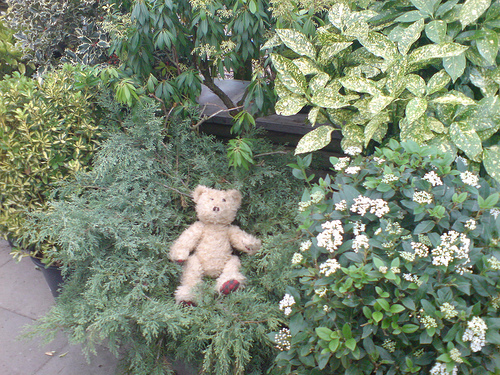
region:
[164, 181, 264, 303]
A teddy bear in the bushes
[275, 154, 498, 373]
bush on bottom right has yellow flowers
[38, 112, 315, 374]
The bear is laying on a fern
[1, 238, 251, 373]
The ground is grey bricks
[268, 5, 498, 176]
Leaves on the top right bush are green and yellow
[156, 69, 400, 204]
Stone wall is behind the bushes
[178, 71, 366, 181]
The stone wall is slate and black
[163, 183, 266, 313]
The bear is furry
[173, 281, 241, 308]
The bottom of his paws are plaid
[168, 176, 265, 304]
The bear is white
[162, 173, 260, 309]
A brown teddy bear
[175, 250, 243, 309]
The bottom of the teddy bears feet are red and black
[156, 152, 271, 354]
The teddy bear lies on top of a bush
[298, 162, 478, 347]
A bush with clusters of white flowers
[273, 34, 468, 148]
A tree with green and yellow leaves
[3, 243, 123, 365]
A grey tiled sidewalk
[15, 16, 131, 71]
Green leaves with yellow borders around them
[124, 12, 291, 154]
A tree with long thin leaves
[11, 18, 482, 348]
A planter next to the sidewalk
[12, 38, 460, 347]
A row of green bushes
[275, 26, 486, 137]
the leaves are green and white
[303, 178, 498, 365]
the white flowers are small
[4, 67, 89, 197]
the bush is green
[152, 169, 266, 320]
the bear is brown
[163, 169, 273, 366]
the bear is not wearing clothes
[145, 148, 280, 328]
the bear is in a bush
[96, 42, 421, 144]
there is a bench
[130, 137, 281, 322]
the bear is laying in the bush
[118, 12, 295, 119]
the tree is green with small leaves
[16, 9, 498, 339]
many greenery surround the bear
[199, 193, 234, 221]
head of a doll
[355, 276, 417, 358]
part of some leaves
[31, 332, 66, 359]
part of a floor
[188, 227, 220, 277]
stomach of a doll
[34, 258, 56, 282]
part of a vase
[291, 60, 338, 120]
part of some leaves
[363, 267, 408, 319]
part of a plant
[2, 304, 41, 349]
part of a floor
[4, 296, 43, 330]
part of a line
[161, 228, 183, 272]
part of a hand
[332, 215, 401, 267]
part of a flower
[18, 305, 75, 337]
part of a floor